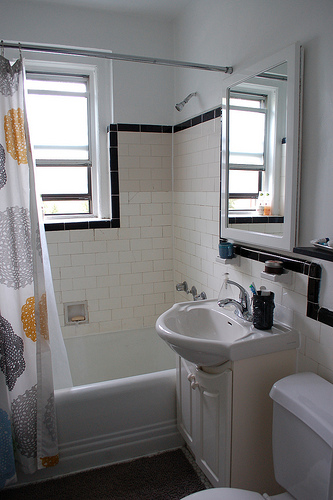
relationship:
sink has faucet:
[153, 284, 292, 370] [220, 279, 251, 321]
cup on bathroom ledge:
[220, 241, 236, 258] [196, 238, 326, 304]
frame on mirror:
[217, 45, 298, 258] [224, 59, 285, 237]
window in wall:
[25, 60, 107, 225] [1, 11, 183, 299]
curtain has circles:
[1, 35, 67, 489] [1, 293, 50, 388]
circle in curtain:
[2, 107, 34, 170] [1, 35, 67, 489]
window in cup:
[0, 45, 112, 224] [252, 286, 276, 331]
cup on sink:
[252, 286, 276, 331] [152, 294, 297, 355]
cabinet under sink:
[170, 357, 248, 472] [153, 297, 292, 360]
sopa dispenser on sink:
[216, 267, 236, 302] [152, 290, 292, 354]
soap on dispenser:
[68, 312, 89, 322] [61, 295, 91, 327]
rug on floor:
[84, 469, 183, 496] [1, 451, 206, 493]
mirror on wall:
[214, 69, 280, 237] [19, 138, 212, 331]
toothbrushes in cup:
[246, 282, 258, 295] [252, 286, 276, 331]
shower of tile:
[166, 84, 201, 127] [90, 265, 111, 276]